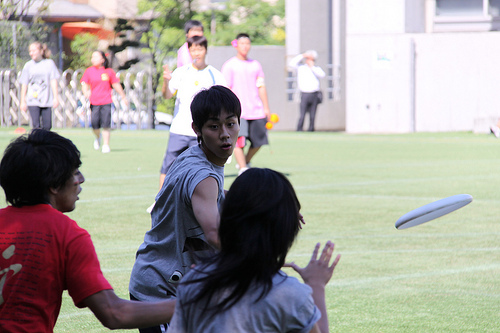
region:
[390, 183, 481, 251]
A white frisbee flying through the air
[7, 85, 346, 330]
Three people playing with a frisbee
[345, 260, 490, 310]
A white line painted on the ground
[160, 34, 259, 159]
A man in a white shirt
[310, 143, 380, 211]
Short grass grows on the ground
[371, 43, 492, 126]
The white wall of a building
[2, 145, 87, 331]
A man wearing a red shirt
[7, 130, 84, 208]
The man's hair is short and dark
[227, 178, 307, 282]
The woman has long, dark hair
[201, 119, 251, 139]
The man's eyes are open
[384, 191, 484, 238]
a frisbee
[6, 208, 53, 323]
a mans shirt is red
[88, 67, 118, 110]
women wearing a red shirt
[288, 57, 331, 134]
a man standing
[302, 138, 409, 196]
a field of green grass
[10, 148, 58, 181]
the mans hair is black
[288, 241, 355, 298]
a persons hand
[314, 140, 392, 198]
a field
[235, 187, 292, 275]
a persons black hair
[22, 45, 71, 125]
a person walking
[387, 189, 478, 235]
White plastic frisbee in air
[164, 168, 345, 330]
Player preparing to catch frisbee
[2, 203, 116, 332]
Red T shirt on player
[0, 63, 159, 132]
Wooden lattice fence in background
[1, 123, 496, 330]
Green grass of playing field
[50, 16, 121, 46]
Open umbrella for shade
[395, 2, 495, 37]
Window on building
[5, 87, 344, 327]
Ultimate frisbee players in shade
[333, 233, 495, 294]
Boundary lines painted on field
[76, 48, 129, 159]
Woman walking on field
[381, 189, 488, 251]
white frisbee in air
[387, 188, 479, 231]
white frisbee flying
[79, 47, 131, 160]
woman in red shirt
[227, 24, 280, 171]
man in pink shirt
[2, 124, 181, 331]
man in red shirt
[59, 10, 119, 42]
orange umbrella behind fence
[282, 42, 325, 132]
man in uniform watching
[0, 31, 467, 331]
people gathered in a field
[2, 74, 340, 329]
people playing frisbee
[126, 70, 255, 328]
woman throwing a frisbee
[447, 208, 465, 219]
part of a floater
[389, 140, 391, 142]
part of a field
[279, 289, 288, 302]
back of a man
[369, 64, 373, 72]
part of a wall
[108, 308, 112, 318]
part of an elbow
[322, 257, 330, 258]
part of a finger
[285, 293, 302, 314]
part of an elbow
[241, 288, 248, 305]
part of a shirt